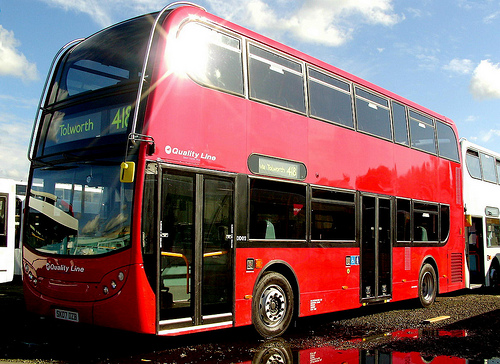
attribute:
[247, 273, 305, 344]
tire — black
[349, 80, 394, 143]
window — small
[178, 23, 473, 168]
window — small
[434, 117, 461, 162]
window — small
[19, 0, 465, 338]
bus — red, double-decker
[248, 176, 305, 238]
window — small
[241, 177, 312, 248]
window — Small 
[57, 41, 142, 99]
window — Small 